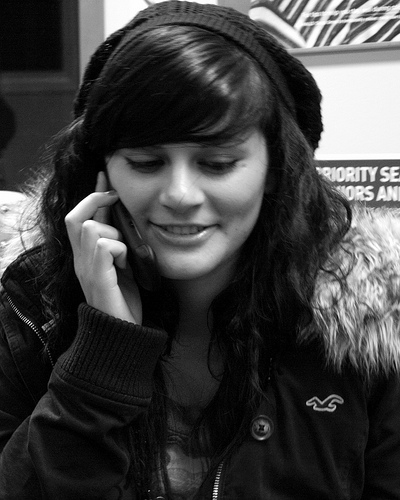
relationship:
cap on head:
[74, 0, 324, 154] [87, 24, 269, 281]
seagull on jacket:
[304, 393, 344, 412] [1, 240, 399, 499]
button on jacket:
[249, 414, 274, 443] [1, 240, 399, 499]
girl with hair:
[1, 21, 399, 497] [18, 23, 353, 404]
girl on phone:
[1, 21, 399, 497] [112, 196, 160, 283]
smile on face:
[144, 220, 222, 248] [105, 117, 270, 280]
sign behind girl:
[314, 158, 400, 206] [1, 21, 399, 497]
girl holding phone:
[1, 21, 399, 497] [112, 196, 160, 283]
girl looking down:
[1, 21, 399, 497] [1, 428, 399, 499]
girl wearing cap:
[1, 21, 399, 497] [74, 0, 324, 154]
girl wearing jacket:
[1, 21, 399, 497] [1, 240, 399, 499]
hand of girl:
[64, 170, 144, 331] [1, 21, 399, 497]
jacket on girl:
[1, 240, 399, 499] [1, 21, 399, 497]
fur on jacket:
[315, 204, 399, 380] [1, 240, 399, 499]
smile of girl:
[144, 220, 222, 248] [1, 21, 399, 497]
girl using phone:
[1, 21, 399, 497] [112, 196, 160, 283]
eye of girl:
[200, 157, 236, 169] [1, 21, 399, 497]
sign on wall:
[314, 158, 400, 206] [2, 2, 400, 209]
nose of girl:
[159, 149, 207, 215] [1, 21, 399, 497]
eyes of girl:
[127, 152, 239, 173] [1, 21, 399, 497]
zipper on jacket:
[209, 458, 225, 498] [1, 240, 399, 499]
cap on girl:
[74, 0, 324, 154] [1, 21, 399, 497]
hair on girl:
[18, 23, 353, 404] [1, 21, 399, 497]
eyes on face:
[127, 152, 239, 173] [105, 117, 270, 280]